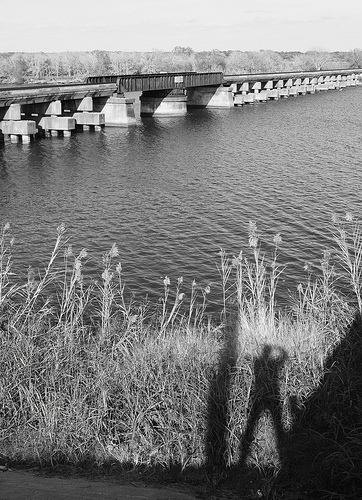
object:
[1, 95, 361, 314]
water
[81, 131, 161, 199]
ground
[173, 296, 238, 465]
trees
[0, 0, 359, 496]
picture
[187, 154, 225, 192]
waves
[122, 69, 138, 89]
cars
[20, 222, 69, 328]
grass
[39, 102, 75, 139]
support pylon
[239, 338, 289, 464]
shadow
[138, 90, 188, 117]
pillar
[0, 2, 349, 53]
sky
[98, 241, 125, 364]
plants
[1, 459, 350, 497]
road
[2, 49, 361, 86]
area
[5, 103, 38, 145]
supports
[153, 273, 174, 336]
weeds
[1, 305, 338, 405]
bank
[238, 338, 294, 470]
body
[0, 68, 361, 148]
bridge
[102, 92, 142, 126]
bridge supports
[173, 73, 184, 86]
sign